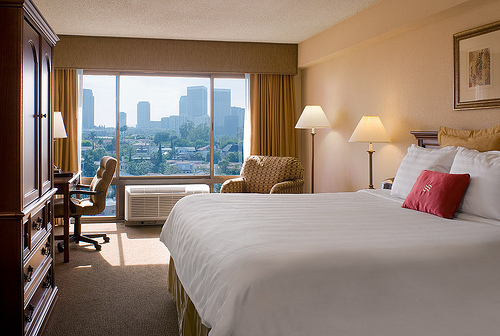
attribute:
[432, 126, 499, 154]
pillow — yellow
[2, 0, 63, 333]
armoire — brown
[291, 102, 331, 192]
lamp — tallest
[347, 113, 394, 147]
shade — white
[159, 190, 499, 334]
sheet — white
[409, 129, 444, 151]
headboard — wooden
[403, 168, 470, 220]
pillow — red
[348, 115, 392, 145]
shade — glowing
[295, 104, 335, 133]
shade — glowing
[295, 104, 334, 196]
lamp — tallest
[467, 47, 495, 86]
picture — square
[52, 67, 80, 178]
curtain — open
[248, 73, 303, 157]
curtain — open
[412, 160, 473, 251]
pillow — red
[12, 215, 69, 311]
furniture — wood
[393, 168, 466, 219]
pillow — red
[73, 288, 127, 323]
carpet — brown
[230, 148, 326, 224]
chair — big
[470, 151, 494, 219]
pillow — white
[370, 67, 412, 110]
wall — tanned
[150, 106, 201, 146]
buildings — tall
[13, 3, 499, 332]
hotel room — clean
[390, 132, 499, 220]
pillows — red, white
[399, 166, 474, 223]
pillow — small, rectangular, red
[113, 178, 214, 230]
air conditioning — white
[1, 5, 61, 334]
dresser — wooden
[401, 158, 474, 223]
pillow — red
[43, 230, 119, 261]
wheels — black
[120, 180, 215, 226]
radiator — long, white